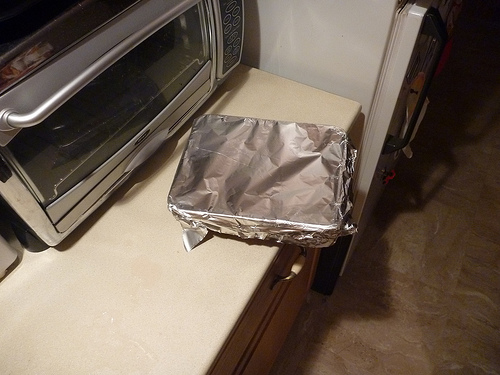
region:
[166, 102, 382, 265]
dish wrapped in aluminum foil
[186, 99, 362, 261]
dish sitting on counter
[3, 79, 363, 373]
counter top is ivory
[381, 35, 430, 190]
black handle of refrigerator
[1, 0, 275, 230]
toaster oven sitting on counter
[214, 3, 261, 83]
key pad on toaster oven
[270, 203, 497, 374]
brown tiles on floor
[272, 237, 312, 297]
ivory handle of kitchen drawer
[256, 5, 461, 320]
refrigerator next to counter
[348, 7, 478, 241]
magnets on refrigerator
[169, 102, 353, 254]
The pan is covered in foil.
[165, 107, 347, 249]
The foil is silver in color.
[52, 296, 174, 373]
The counter top is white.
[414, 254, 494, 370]
The floor is biege in color.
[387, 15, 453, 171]
The fridge door handle is black.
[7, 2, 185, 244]
The toaster oven is silver.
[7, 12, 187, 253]
The toaster oven is on the counter.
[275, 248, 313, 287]
The cabinet knob is white and gold.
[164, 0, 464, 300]
a white colored refrigerator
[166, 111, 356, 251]
a pan covered with silver aluminum foil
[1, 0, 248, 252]
a digitally controlled toaster oven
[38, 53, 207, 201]
a silver colored metal rack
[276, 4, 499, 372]
a brown and tan floor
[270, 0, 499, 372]
dark shadows on the floor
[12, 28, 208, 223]
reflection of aluminum foil in the glass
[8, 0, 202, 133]
silver handle on the toaster oven door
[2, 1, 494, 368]
A kitchen with appliances.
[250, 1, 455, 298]
Refrigerator next to a counter.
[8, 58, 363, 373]
A counter top in a kitchen.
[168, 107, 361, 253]
A baking dish on a counter.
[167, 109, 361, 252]
Aluminum foil on a baking dish.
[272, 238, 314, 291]
The handle of a cabinet drawer.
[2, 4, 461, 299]
A microwave and a refrigerator beside each other.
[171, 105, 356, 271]
pan covered with foil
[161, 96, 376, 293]
pan covered with foil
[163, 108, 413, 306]
pan covered with foil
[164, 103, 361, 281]
pan covered with foil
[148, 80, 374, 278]
a container on the countertop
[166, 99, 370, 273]
a container on the countertop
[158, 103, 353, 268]
a container on the countertop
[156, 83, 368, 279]
a container on the countertop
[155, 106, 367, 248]
a dish covered in aluminum foil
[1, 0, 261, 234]
an electronic oven with glass door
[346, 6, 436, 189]
the handle of a fridge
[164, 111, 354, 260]
container is covered in foil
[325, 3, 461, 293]
refrigerator door is closed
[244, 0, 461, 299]
refridgerator is in kitchen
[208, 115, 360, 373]
drawer is closed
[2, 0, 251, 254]
toaster oven is closed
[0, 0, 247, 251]
toaster oven rests on counter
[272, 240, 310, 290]
handle is attached to drawer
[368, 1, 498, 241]
shadow is cast by refridgerator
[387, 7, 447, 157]
handle is attached to refridgerator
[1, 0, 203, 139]
handle is attached to toaster oven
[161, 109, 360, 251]
Foil covered baking dish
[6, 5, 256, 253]
Stainless steel toaster oven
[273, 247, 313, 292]
Ceramic drawer pull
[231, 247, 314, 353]
Wooden drawer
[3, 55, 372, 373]
Light colored counter top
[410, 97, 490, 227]
Shadow of refrigerator door handles on the floor